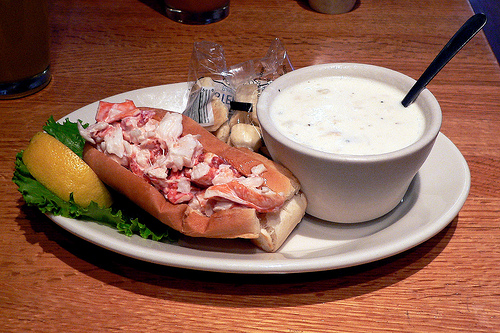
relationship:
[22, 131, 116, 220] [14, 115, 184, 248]
lemon wedge on top of lettuce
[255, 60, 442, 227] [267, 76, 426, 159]
bowl has soup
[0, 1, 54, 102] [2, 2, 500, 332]
glass on top of table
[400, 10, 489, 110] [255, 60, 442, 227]
spoon in bowl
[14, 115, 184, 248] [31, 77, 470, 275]
lettuce on top of plate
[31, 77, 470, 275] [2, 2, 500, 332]
plate on top of table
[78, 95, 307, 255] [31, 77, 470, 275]
lobster sandwich on top of plate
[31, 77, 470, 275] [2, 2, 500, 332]
plate sits on top of table